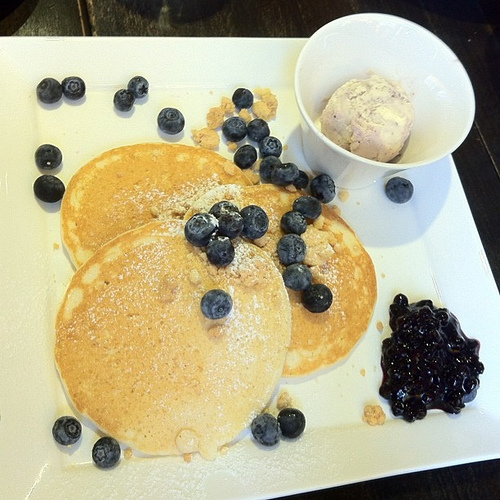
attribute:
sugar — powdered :
[228, 181, 240, 196]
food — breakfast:
[18, 137, 380, 341]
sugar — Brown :
[192, 91, 226, 151]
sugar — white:
[141, 178, 232, 219]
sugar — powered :
[206, 260, 288, 420]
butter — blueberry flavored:
[352, 81, 422, 143]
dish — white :
[292, 12, 476, 191]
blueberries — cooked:
[398, 313, 467, 390]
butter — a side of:
[331, 56, 426, 173]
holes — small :
[150, 333, 166, 342]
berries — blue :
[108, 75, 165, 119]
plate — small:
[392, 212, 482, 294]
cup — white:
[284, 7, 487, 199]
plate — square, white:
[1, 30, 484, 485]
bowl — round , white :
[294, 11, 475, 172]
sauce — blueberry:
[382, 282, 489, 427]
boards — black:
[51, 2, 300, 34]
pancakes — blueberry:
[58, 133, 374, 462]